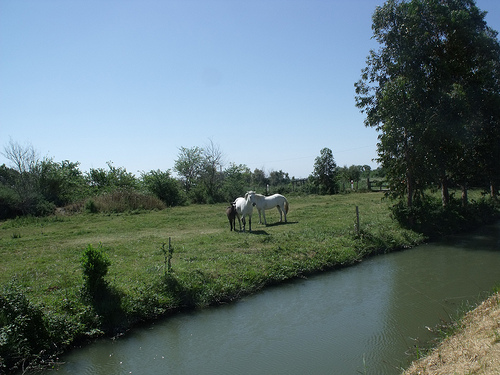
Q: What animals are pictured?
A: Horses.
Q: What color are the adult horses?
A: White.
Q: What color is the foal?
A: Brown.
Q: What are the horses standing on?
A: Grass.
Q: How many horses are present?
A: Three.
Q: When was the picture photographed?
A: During the day.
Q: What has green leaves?
A: Trees.